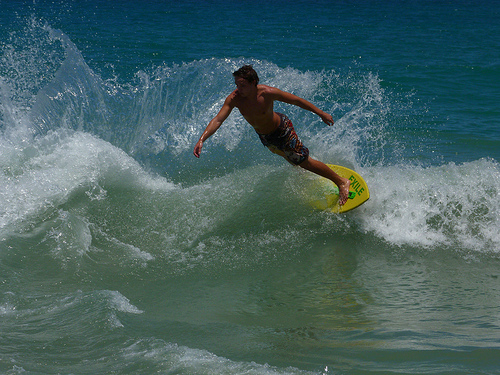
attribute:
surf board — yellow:
[295, 165, 387, 221]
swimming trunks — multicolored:
[250, 110, 307, 157]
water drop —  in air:
[125, 15, 128, 17]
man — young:
[194, 66, 351, 205]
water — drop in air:
[32, 82, 175, 284]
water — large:
[86, 77, 424, 324]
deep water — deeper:
[80, 66, 225, 281]